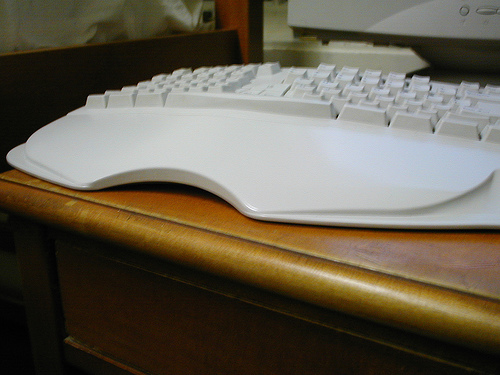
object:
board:
[0, 166, 497, 317]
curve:
[89, 169, 500, 216]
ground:
[324, 131, 381, 196]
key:
[89, 63, 500, 136]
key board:
[7, 63, 497, 231]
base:
[402, 44, 499, 86]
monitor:
[286, 2, 498, 41]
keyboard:
[8, 63, 499, 237]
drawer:
[49, 237, 493, 373]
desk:
[0, 168, 500, 374]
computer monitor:
[284, 0, 500, 40]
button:
[458, 4, 468, 16]